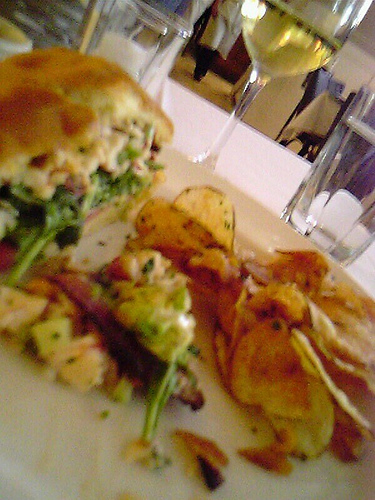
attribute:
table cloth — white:
[198, 91, 355, 208]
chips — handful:
[134, 180, 371, 465]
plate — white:
[19, 110, 371, 486]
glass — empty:
[69, 12, 195, 99]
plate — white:
[3, 137, 373, 499]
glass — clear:
[282, 84, 373, 272]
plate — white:
[68, 196, 371, 482]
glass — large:
[189, 0, 374, 180]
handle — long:
[190, 67, 270, 168]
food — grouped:
[15, 44, 373, 450]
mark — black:
[269, 321, 284, 333]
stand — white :
[191, 71, 269, 174]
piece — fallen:
[124, 418, 245, 491]